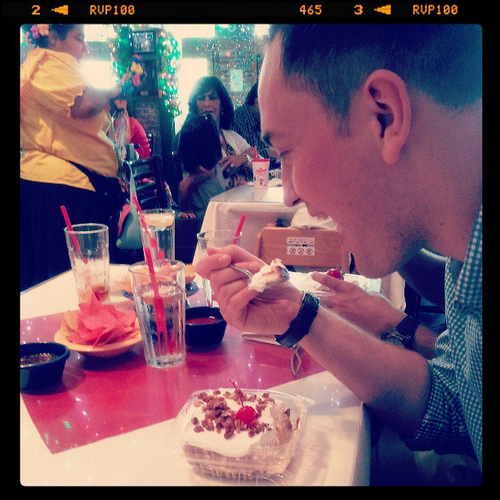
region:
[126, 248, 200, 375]
water glass with red straw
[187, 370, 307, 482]
dessert with a cherry on top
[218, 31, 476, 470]
man eating dessert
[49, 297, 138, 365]
small bowl of red chips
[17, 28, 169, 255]
woman in yellow shirt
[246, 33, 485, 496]
man in blue checkered shirt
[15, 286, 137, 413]
chips and salsa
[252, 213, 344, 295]
back of a high chair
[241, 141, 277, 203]
white plastic cup with red straw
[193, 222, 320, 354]
fork with a bite of food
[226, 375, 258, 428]
a red cherry with a stem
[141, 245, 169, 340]
a red straw in a water glass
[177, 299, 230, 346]
a cup of salsa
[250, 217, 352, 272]
a wooden high chair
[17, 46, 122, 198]
a yellow shirt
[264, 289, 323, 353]
a black watch band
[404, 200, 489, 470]
a blue checkered shirt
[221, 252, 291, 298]
a bite of dessert on a spoon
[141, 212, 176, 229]
a lemon slice floating in a glass of water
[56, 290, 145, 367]
corn chips in a yellow bowl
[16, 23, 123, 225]
Woman in yellow top with a flower in her hair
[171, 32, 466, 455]
Man eating a small pastry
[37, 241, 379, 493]
White table with glasses and food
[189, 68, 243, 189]
Woman with long black hair wearing a white shirt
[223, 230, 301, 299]
Spoon laden with a spoonful of pastry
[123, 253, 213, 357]
Glass with a clear liquid and a red straw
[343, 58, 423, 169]
Man's pink colored ear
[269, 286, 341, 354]
Black watch on man's right hand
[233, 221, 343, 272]
Empty brown wooden chair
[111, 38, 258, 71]
Colorful decorations on a wall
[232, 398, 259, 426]
a small red cherry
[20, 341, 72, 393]
a small dip bowl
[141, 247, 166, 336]
a long red straw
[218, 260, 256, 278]
a clear plastic spoon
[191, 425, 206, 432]
a small brown nut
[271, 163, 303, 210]
the nose of a man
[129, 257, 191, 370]
a tall clear glass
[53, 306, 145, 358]
a bowl of tortilla chips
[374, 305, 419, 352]
a black watch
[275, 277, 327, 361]
a man's wrist watch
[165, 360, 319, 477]
a white dessert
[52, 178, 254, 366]
four glasses of drinks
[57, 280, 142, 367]
a bowl of chips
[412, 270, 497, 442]
a green and white shirt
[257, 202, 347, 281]
a child's high chair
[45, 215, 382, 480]
a table with dishes and glasses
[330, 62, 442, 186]
a man's ear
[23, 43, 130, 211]
a woman in a yellow top